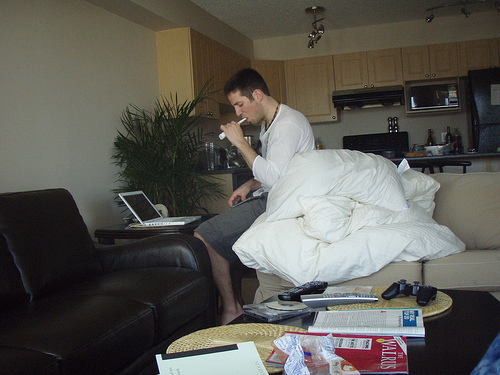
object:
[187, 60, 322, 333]
man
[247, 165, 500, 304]
sofa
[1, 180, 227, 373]
sofa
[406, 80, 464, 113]
microwave oven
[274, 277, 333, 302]
remote control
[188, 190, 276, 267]
shorts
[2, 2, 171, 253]
wall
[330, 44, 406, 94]
cabinet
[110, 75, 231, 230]
plant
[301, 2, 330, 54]
light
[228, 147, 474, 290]
blanket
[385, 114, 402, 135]
salt&pepper shakers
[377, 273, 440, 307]
remote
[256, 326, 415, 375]
valrus magazine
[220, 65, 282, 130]
head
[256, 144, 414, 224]
pillows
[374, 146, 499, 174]
counter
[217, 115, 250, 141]
toothbrush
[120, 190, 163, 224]
screen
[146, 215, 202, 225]
keyboard area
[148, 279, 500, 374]
table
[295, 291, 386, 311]
remote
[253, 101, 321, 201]
shirt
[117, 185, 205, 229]
computer